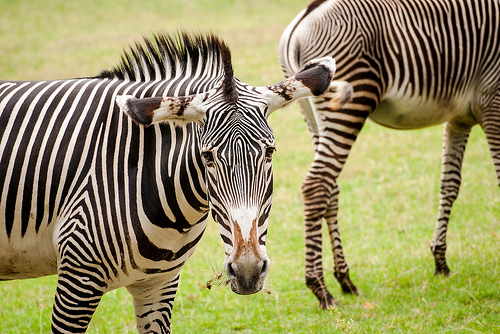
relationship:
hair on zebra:
[73, 26, 240, 105] [1, 27, 336, 331]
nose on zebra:
[222, 256, 270, 294] [1, 27, 336, 331]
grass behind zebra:
[1, 0, 498, 332] [1, 27, 336, 331]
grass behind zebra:
[1, 0, 498, 332] [276, 27, 497, 312]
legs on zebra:
[301, 81, 390, 311] [276, 27, 497, 312]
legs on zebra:
[299, 101, 359, 295] [276, 27, 497, 312]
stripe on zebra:
[391, 16, 414, 94] [275, 0, 499, 312]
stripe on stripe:
[399, 0, 433, 106] [391, 16, 414, 94]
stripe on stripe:
[417, 0, 432, 35] [391, 16, 414, 94]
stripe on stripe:
[447, 1, 459, 106] [391, 16, 414, 94]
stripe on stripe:
[440, 168, 461, 177] [391, 16, 414, 94]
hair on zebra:
[86, 26, 235, 105] [94, 25, 251, 98]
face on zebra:
[186, 82, 278, 296] [1, 27, 336, 331]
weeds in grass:
[375, 170, 423, 240] [358, 230, 428, 332]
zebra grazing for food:
[1, 27, 336, 331] [196, 261, 288, 308]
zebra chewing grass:
[1, 27, 336, 331] [1, 0, 498, 332]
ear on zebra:
[253, 56, 335, 113] [1, 27, 336, 331]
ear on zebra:
[113, 92, 208, 127] [275, 0, 499, 312]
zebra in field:
[1, 27, 336, 331] [6, 28, 497, 332]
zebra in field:
[276, 27, 497, 312] [6, 28, 497, 332]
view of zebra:
[108, 36, 288, 317] [1, 27, 336, 331]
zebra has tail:
[275, 0, 499, 312] [280, 15, 355, 110]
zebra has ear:
[1, 27, 336, 331] [115, 89, 237, 152]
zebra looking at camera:
[1, 27, 336, 331] [255, 235, 402, 326]